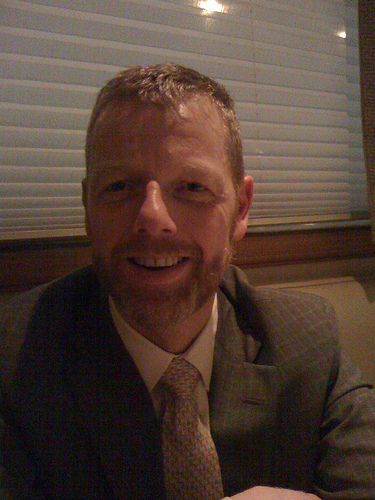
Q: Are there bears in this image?
A: No, there are no bears.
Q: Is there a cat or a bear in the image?
A: No, there are no bears or cats.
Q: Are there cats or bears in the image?
A: No, there are no bears or cats.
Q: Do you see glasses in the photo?
A: No, there are no glasses.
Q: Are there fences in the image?
A: No, there are no fences.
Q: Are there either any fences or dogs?
A: No, there are no fences or dogs.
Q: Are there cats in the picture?
A: No, there are no cats.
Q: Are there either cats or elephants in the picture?
A: No, there are no cats or elephants.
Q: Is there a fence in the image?
A: No, there are no fences.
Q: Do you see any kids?
A: No, there are no kids.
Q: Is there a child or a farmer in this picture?
A: No, there are no children or farmers.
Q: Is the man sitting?
A: Yes, the man is sitting.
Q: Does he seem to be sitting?
A: Yes, the man is sitting.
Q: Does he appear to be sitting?
A: Yes, the man is sitting.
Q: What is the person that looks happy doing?
A: The man is sitting.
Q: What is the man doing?
A: The man is sitting.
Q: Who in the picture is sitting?
A: The man is sitting.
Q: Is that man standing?
A: No, the man is sitting.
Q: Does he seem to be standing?
A: No, the man is sitting.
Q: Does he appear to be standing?
A: No, the man is sitting.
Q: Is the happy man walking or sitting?
A: The man is sitting.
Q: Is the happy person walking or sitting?
A: The man is sitting.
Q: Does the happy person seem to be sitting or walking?
A: The man is sitting.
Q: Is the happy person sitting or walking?
A: The man is sitting.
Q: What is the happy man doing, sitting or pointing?
A: The man is sitting.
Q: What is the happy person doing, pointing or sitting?
A: The man is sitting.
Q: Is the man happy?
A: Yes, the man is happy.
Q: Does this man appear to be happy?
A: Yes, the man is happy.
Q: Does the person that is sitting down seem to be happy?
A: Yes, the man is happy.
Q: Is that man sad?
A: No, the man is happy.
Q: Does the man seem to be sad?
A: No, the man is happy.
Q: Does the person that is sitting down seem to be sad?
A: No, the man is happy.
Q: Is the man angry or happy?
A: The man is happy.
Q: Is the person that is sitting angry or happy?
A: The man is happy.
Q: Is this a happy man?
A: Yes, this is a happy man.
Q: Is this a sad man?
A: No, this is a happy man.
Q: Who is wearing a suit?
A: The man is wearing a suit.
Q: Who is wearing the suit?
A: The man is wearing a suit.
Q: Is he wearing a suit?
A: Yes, the man is wearing a suit.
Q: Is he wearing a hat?
A: No, the man is wearing a suit.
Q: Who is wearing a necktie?
A: The man is wearing a necktie.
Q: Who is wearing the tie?
A: The man is wearing a necktie.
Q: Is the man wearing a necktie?
A: Yes, the man is wearing a necktie.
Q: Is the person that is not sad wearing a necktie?
A: Yes, the man is wearing a necktie.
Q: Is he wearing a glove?
A: No, the man is wearing a necktie.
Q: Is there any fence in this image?
A: No, there are no fences.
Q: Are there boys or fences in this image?
A: No, there are no fences or boys.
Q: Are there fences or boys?
A: No, there are no fences or boys.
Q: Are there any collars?
A: Yes, there is a collar.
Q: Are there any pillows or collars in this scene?
A: Yes, there is a collar.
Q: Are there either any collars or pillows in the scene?
A: Yes, there is a collar.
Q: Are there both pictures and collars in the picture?
A: No, there is a collar but no pictures.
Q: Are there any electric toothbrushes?
A: No, there are no electric toothbrushes.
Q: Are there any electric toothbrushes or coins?
A: No, there are no electric toothbrushes or coins.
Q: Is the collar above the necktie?
A: Yes, the collar is above the necktie.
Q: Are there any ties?
A: Yes, there is a tie.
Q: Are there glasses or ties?
A: Yes, there is a tie.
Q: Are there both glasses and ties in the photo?
A: No, there is a tie but no glasses.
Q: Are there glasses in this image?
A: No, there are no glasses.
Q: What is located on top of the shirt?
A: The necktie is on top of the shirt.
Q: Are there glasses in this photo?
A: No, there are no glasses.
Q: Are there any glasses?
A: No, there are no glasses.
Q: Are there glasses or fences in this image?
A: No, there are no glasses or fences.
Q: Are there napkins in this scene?
A: No, there are no napkins.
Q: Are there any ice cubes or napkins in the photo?
A: No, there are no napkins or ice cubes.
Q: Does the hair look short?
A: Yes, the hair is short.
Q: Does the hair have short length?
A: Yes, the hair is short.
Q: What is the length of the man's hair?
A: The hair is short.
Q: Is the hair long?
A: No, the hair is short.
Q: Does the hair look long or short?
A: The hair is short.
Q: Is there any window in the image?
A: Yes, there is a window.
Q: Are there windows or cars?
A: Yes, there is a window.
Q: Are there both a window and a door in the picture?
A: No, there is a window but no doors.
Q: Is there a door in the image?
A: No, there are no doors.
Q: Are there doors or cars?
A: No, there are no doors or cars.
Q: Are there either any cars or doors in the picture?
A: No, there are no doors or cars.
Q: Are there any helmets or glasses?
A: No, there are no glasses or helmets.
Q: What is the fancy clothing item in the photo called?
A: The clothing item is a suit.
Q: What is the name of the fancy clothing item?
A: The clothing item is a suit.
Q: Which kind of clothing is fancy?
A: The clothing is a suit.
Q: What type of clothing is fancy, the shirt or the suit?
A: The suit is fancy.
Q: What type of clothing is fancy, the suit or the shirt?
A: The suit is fancy.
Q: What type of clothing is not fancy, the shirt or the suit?
A: The shirt is not fancy.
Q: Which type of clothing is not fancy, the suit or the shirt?
A: The shirt is not fancy.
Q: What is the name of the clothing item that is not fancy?
A: The clothing item is a shirt.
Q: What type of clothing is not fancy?
A: The clothing is a shirt.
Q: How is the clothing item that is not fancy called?
A: The clothing item is a shirt.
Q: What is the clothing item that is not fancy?
A: The clothing item is a shirt.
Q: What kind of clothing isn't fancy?
A: The clothing is a shirt.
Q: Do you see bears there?
A: No, there are no bears.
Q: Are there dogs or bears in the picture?
A: No, there are no bears or dogs.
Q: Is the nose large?
A: Yes, the nose is large.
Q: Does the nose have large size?
A: Yes, the nose is large.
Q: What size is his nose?
A: The nose is large.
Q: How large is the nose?
A: The nose is large.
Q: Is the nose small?
A: No, the nose is large.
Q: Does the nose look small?
A: No, the nose is large.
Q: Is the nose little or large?
A: The nose is large.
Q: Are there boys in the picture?
A: No, there are no boys.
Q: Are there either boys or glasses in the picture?
A: No, there are no boys or glasses.